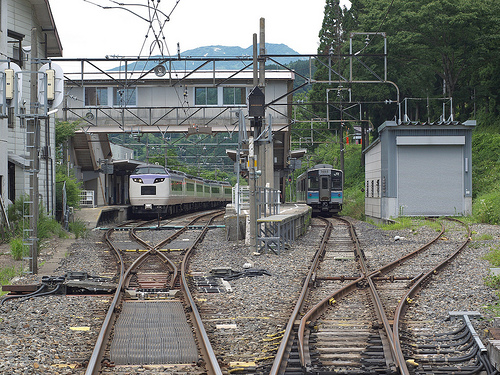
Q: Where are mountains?
A: In the far distance.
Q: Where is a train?
A: On train tracks.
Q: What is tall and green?
A: Trees.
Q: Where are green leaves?
A: On the trees.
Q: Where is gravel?
A: On the ground.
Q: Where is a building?
A: Next to the tracks.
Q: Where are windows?
A: On a building.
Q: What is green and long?
A: Grass.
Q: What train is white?
A: Train on left.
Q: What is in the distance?
A: Mountains.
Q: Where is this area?
A: Rural.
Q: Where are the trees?
A: On right side.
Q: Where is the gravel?
A: On ground near tracks.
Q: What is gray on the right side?
A: Shed.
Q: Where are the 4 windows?
A: On the cream building above train.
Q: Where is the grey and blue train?
A: On right of track.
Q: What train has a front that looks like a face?
A: Train on left.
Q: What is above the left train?
A: Building.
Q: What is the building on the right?
A: Garage.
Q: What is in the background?
A: Mountain.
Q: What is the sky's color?
A: White.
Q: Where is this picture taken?
A: Train switching station.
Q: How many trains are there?
A: 2.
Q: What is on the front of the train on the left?
A: Painted eyes.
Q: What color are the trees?
A: Green.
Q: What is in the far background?
A: A mountain.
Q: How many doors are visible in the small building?
A: 1.